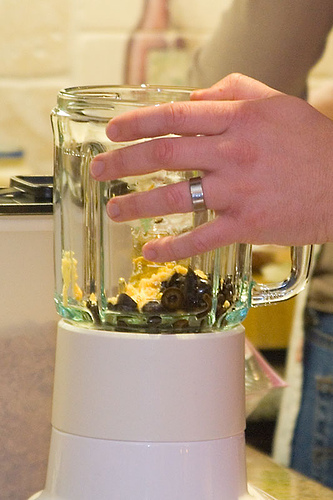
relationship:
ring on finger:
[186, 175, 207, 215] [106, 177, 218, 223]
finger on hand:
[106, 177, 218, 223] [88, 71, 333, 263]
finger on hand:
[141, 218, 230, 263] [88, 71, 333, 263]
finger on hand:
[87, 136, 220, 182] [88, 71, 333, 263]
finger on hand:
[104, 100, 231, 144] [88, 71, 333, 263]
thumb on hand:
[188, 71, 270, 101] [88, 71, 333, 263]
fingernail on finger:
[142, 247, 156, 261] [141, 218, 230, 263]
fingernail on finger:
[106, 200, 120, 219] [106, 177, 218, 223]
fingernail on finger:
[87, 158, 105, 180] [87, 136, 220, 182]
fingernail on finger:
[106, 123, 120, 139] [104, 100, 231, 144]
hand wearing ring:
[88, 71, 333, 263] [186, 175, 207, 215]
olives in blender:
[96, 271, 240, 334] [46, 86, 315, 334]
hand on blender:
[88, 71, 333, 263] [46, 86, 315, 334]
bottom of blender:
[42, 319, 248, 500] [46, 86, 315, 334]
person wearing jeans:
[181, 13, 333, 491] [289, 303, 333, 489]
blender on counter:
[46, 86, 315, 334] [243, 436, 333, 498]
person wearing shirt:
[181, 13, 333, 491] [184, 1, 332, 312]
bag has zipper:
[246, 334, 291, 426] [250, 337, 291, 392]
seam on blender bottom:
[50, 421, 248, 451] [42, 319, 248, 500]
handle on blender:
[251, 244, 315, 308] [46, 86, 315, 334]